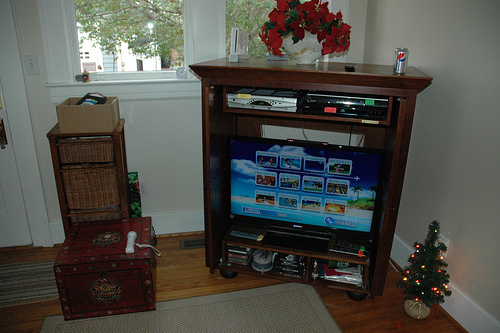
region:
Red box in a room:
[44, 208, 170, 322]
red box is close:
[46, 206, 167, 324]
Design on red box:
[81, 273, 126, 310]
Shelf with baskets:
[38, 111, 135, 226]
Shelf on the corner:
[167, 43, 437, 303]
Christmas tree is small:
[394, 215, 459, 324]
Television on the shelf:
[209, 123, 384, 247]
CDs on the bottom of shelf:
[217, 242, 306, 279]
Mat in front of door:
[0, 254, 70, 308]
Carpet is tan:
[36, 273, 346, 332]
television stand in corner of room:
[185, 31, 414, 318]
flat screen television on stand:
[218, 126, 385, 261]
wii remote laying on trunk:
[119, 227, 159, 264]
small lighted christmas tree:
[397, 205, 459, 327]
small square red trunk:
[48, 210, 187, 320]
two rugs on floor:
[11, 248, 353, 331]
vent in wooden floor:
[170, 229, 215, 254]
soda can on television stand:
[389, 40, 413, 87]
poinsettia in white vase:
[256, 5, 358, 76]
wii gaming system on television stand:
[224, 18, 254, 71]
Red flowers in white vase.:
[260, 1, 351, 54]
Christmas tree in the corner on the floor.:
[400, 217, 451, 308]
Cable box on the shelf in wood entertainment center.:
[225, 91, 298, 112]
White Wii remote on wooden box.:
[118, 225, 140, 258]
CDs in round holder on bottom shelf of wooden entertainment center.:
[255, 251, 272, 268]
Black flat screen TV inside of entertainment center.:
[228, 135, 382, 235]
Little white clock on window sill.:
[172, 66, 191, 78]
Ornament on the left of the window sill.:
[76, 69, 91, 86]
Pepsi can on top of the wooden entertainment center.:
[393, 41, 408, 73]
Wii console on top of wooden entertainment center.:
[222, 23, 249, 62]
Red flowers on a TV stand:
[257, 3, 364, 90]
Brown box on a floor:
[41, 215, 166, 310]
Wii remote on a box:
[104, 222, 167, 259]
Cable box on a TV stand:
[205, 72, 418, 133]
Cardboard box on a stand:
[47, 90, 169, 281]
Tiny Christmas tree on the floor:
[386, 175, 471, 326]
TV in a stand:
[205, 110, 375, 245]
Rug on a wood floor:
[171, 257, 399, 323]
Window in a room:
[33, 2, 270, 113]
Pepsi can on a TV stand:
[375, 35, 438, 122]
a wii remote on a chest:
[113, 230, 168, 257]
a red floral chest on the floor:
[54, 220, 170, 322]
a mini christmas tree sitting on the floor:
[401, 221, 453, 327]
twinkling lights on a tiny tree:
[414, 274, 425, 285]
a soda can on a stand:
[393, 31, 424, 86]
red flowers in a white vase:
[248, 0, 363, 40]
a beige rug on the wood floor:
[206, 289, 340, 322]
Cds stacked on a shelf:
[234, 243, 279, 275]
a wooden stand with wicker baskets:
[49, 133, 135, 220]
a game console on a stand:
[221, 20, 256, 64]